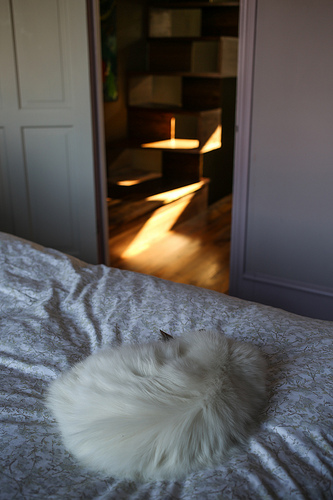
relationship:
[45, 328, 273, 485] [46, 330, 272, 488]
cat has fur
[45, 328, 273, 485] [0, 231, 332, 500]
cat on top of bed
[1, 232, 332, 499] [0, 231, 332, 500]
sheet on top of bed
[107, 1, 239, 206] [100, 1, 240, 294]
boxes inside room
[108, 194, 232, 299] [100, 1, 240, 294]
floor inside room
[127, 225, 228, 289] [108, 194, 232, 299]
sunlight shining on floor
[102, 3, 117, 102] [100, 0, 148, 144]
poster hanging on wall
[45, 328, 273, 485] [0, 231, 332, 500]
cat sleeping on bed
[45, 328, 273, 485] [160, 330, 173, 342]
cat has ear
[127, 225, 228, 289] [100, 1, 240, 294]
sunlight shining in room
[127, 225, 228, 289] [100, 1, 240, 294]
sunlight reflecting in room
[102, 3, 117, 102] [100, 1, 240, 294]
poster hanging in room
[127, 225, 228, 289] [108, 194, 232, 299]
sunlight reflected on floor